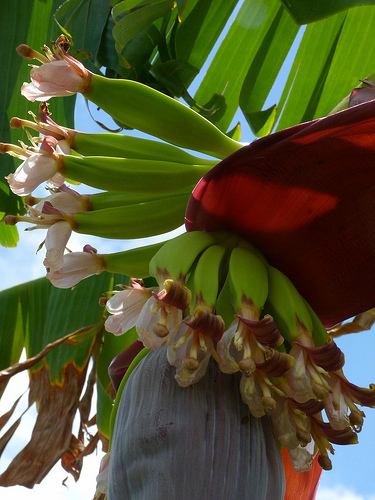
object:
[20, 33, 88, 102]
flower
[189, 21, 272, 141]
leaves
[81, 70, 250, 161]
stem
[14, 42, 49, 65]
bulb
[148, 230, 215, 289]
banana